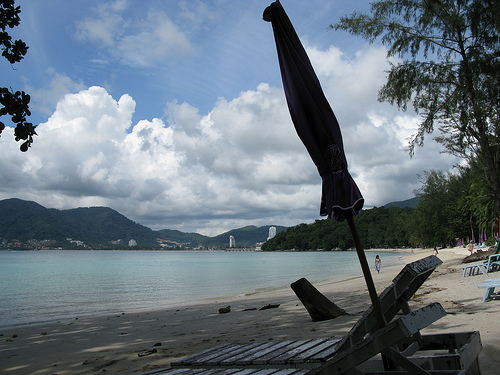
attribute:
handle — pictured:
[408, 252, 458, 278]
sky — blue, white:
[12, 3, 499, 228]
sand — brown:
[3, 245, 497, 372]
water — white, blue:
[5, 247, 462, 325]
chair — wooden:
[172, 238, 449, 368]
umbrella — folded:
[257, 0, 396, 326]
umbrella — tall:
[256, 3, 436, 373]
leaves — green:
[1, 0, 499, 248]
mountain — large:
[3, 192, 281, 258]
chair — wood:
[165, 254, 481, 374]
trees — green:
[246, 191, 487, 261]